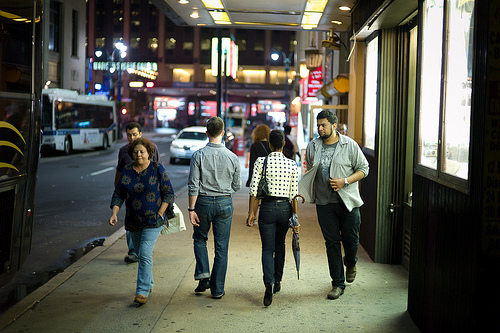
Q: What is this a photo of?
A: A city sidewalk.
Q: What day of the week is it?
A: Tuesday.